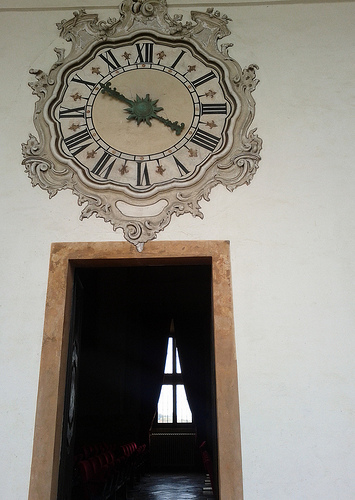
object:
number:
[133, 41, 155, 69]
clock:
[19, 0, 265, 232]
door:
[55, 255, 243, 499]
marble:
[217, 240, 234, 482]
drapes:
[77, 271, 173, 444]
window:
[153, 338, 196, 429]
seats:
[76, 440, 144, 483]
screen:
[58, 279, 94, 456]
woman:
[68, 369, 77, 425]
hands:
[146, 92, 185, 134]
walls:
[264, 24, 355, 463]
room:
[64, 261, 217, 495]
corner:
[204, 238, 233, 265]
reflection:
[154, 475, 200, 499]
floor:
[115, 450, 206, 497]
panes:
[156, 383, 174, 423]